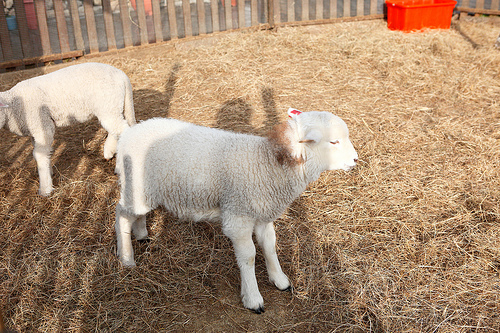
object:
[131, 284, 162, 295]
hay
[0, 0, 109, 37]
fence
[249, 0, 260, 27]
slat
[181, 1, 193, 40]
slat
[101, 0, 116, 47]
slat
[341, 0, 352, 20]
slat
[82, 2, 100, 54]
slat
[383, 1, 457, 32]
plastic container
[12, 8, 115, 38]
wood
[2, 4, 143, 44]
wooden pen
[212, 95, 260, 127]
shadows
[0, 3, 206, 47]
pen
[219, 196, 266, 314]
legs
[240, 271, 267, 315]
hooves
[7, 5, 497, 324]
picture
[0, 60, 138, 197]
lamb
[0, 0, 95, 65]
pen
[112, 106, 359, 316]
sheep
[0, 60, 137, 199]
sheep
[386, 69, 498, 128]
straw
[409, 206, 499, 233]
hay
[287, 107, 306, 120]
ear tag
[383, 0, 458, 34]
bin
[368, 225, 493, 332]
ground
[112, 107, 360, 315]
lamb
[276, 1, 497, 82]
outdoors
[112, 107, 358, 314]
stand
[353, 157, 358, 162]
nose